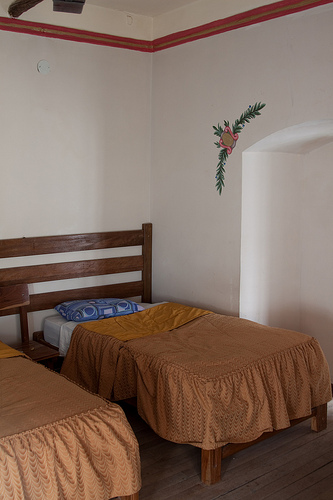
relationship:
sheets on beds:
[6, 303, 313, 481] [0, 221, 332, 498]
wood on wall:
[6, 0, 88, 37] [1, 1, 156, 298]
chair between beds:
[2, 281, 66, 370] [0, 221, 332, 498]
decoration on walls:
[184, 96, 268, 197] [155, 0, 332, 348]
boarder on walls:
[2, 1, 331, 59] [4, 0, 332, 358]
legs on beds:
[117, 392, 333, 499] [0, 221, 332, 498]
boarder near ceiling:
[2, 1, 331, 59] [91, 2, 201, 18]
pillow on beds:
[49, 297, 148, 320] [0, 221, 332, 486]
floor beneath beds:
[99, 398, 331, 499] [0, 221, 332, 498]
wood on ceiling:
[6, 0, 88, 37] [91, 2, 201, 18]